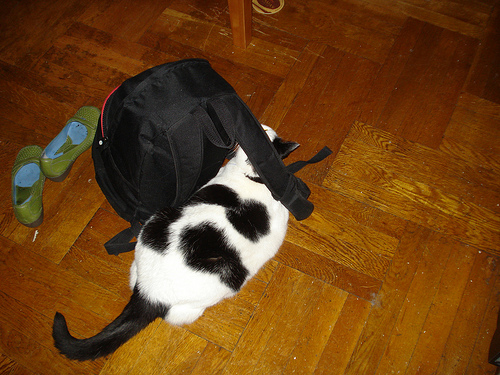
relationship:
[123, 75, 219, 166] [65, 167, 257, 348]
bag near cat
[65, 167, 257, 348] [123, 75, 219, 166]
cat under bag